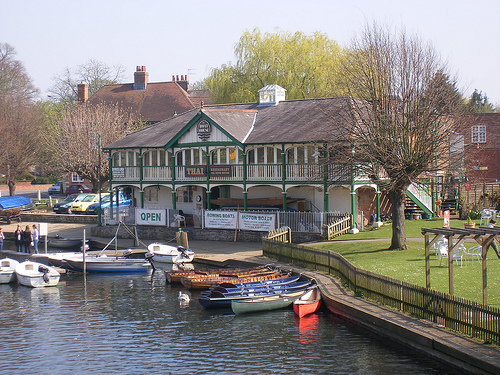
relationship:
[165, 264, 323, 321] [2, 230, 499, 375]
boats tied to wall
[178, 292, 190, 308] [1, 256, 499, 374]
bird in water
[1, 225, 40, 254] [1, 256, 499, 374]
people near water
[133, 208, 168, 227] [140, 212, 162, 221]
sign with letters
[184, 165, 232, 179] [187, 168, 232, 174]
sign with yellow letters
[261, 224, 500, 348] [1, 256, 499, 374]
fence near water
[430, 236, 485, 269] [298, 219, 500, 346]
chairs on lawn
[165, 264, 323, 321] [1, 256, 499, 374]
boats in water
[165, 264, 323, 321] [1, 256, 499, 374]
boats on water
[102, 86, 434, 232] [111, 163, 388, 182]
building with balcony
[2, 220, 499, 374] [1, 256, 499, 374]
sidewalk near water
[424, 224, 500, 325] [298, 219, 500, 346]
gazebo in park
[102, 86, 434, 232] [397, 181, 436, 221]
building has stairs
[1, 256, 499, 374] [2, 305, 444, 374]
water has ripples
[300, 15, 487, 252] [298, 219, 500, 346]
tree in park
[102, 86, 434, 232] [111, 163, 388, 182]
building has balcony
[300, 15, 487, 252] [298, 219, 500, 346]
tree on lawn